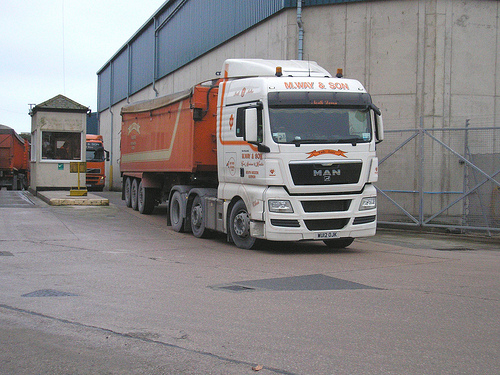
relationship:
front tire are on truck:
[229, 199, 257, 250] [118, 56, 380, 255]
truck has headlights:
[118, 56, 380, 255] [262, 200, 381, 214]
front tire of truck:
[225, 198, 255, 250] [118, 56, 380, 255]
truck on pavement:
[118, 56, 380, 255] [6, 192, 496, 373]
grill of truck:
[254, 187, 382, 247] [118, 56, 380, 255]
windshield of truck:
[260, 98, 386, 142] [118, 56, 380, 255]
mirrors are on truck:
[260, 98, 386, 142] [118, 56, 380, 255]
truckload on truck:
[108, 88, 222, 181] [118, 56, 380, 255]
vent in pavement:
[216, 278, 264, 297] [6, 192, 496, 373]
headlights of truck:
[262, 200, 381, 214] [118, 56, 380, 255]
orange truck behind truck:
[82, 131, 111, 188] [118, 56, 380, 255]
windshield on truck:
[260, 98, 386, 142] [118, 56, 380, 255]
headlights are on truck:
[262, 200, 381, 214] [118, 56, 380, 255]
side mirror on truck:
[234, 105, 269, 150] [118, 56, 380, 255]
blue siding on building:
[95, 0, 281, 114] [99, 1, 492, 235]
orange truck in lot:
[82, 131, 111, 188] [3, 119, 499, 302]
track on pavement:
[1, 190, 28, 212] [0, 192, 500, 374]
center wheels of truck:
[159, 183, 220, 238] [118, 56, 380, 255]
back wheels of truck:
[119, 173, 161, 215] [118, 56, 380, 255]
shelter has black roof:
[27, 93, 93, 191] [26, 96, 93, 113]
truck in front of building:
[118, 56, 380, 255] [99, 1, 492, 235]